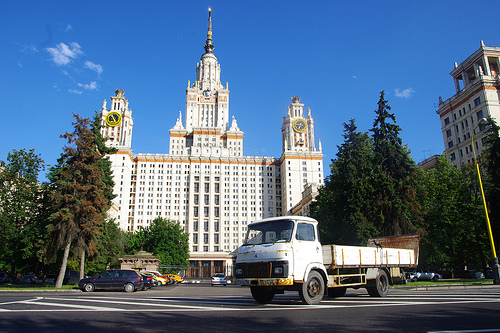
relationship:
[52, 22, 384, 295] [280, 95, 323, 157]
building with tower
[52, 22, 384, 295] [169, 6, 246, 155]
building with tower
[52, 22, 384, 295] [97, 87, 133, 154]
building with tower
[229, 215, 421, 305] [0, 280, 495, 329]
truck in parking lot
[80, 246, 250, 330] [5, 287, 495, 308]
parking lot with lines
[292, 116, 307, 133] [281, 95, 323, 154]
clock on tower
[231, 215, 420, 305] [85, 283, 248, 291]
truck parked in parking lot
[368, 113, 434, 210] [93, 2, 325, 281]
trees growing in front building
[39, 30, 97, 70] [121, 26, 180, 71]
clouds in sky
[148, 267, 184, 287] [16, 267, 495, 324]
car parked in parkinglot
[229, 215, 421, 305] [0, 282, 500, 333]
truck parked on ground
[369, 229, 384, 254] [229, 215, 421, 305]
bird perched on truck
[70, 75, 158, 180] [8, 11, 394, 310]
tower on a building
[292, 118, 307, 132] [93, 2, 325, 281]
clock on building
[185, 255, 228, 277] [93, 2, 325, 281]
entrance of building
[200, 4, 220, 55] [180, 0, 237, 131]
spike on top of tower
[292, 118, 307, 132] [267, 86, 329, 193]
clock on tower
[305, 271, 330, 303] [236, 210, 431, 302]
tire on truck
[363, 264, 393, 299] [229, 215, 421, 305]
tire on truck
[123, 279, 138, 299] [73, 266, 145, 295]
tire on car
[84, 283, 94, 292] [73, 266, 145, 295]
tire on car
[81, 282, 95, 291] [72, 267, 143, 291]
tire on car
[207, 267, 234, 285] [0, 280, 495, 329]
car in parking lot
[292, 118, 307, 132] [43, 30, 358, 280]
clock on building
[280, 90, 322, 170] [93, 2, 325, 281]
tower on building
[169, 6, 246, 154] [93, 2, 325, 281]
tower on building